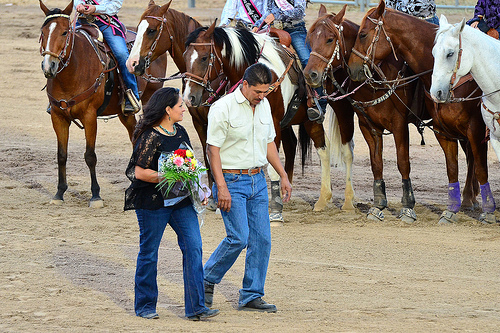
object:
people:
[206, 64, 290, 318]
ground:
[1, 10, 497, 333]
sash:
[242, 2, 268, 33]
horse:
[431, 13, 500, 171]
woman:
[118, 86, 215, 322]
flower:
[172, 156, 185, 167]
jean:
[203, 175, 280, 302]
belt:
[223, 167, 265, 175]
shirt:
[207, 91, 279, 170]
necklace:
[158, 124, 177, 135]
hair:
[129, 87, 176, 144]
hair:
[245, 63, 273, 85]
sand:
[0, 121, 491, 333]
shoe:
[239, 294, 278, 313]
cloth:
[480, 184, 496, 213]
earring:
[169, 115, 171, 122]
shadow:
[41, 234, 175, 316]